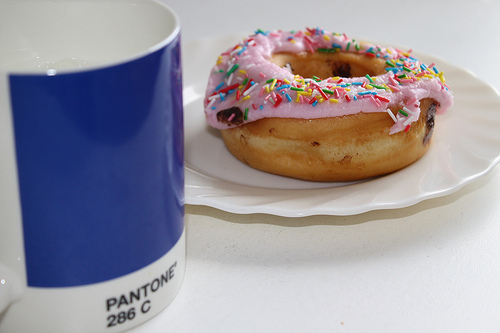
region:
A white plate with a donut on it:
[184, 52, 498, 218]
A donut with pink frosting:
[204, 26, 453, 181]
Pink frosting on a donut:
[204, 29, 453, 135]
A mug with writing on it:
[0, 0, 185, 331]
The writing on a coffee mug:
[104, 263, 178, 328]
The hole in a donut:
[284, 57, 373, 82]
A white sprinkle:
[387, 107, 397, 124]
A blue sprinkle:
[359, 89, 374, 96]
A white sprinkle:
[244, 81, 259, 96]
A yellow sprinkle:
[272, 78, 277, 89]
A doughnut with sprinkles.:
[172, 14, 499, 229]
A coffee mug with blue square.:
[0, 0, 220, 324]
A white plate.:
[175, 103, 494, 225]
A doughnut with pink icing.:
[198, 23, 452, 182]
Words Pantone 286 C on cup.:
[86, 258, 207, 330]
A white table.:
[142, 15, 496, 322]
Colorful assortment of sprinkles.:
[216, 62, 463, 117]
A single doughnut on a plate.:
[178, 8, 498, 255]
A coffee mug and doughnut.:
[0, 3, 499, 331]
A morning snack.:
[0, 1, 486, 320]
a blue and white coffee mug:
[0, 2, 200, 329]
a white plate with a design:
[147, 44, 497, 220]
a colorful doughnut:
[194, 20, 461, 195]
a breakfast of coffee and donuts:
[3, 0, 470, 331]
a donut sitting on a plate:
[151, 11, 498, 234]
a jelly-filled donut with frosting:
[185, 17, 468, 189]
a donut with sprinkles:
[198, 18, 463, 195]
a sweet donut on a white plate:
[140, 14, 498, 231]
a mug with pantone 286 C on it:
[0, 2, 212, 332]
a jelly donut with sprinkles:
[193, 15, 469, 190]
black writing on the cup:
[101, 256, 182, 330]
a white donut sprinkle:
[241, 80, 261, 96]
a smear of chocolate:
[215, 103, 246, 125]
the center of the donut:
[266, 42, 388, 82]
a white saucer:
[181, 35, 498, 226]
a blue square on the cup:
[6, 20, 187, 292]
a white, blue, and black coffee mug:
[1, 0, 191, 331]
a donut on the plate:
[198, 24, 455, 186]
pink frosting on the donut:
[196, 25, 455, 139]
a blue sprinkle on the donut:
[356, 88, 378, 99]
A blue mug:
[0, 2, 187, 315]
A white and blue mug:
[11, 0, 193, 298]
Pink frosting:
[205, 14, 457, 139]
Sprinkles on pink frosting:
[205, 23, 460, 188]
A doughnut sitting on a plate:
[200, 20, 499, 195]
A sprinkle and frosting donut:
[194, 10, 482, 214]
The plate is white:
[193, 7, 498, 232]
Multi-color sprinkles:
[191, 11, 480, 233]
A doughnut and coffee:
[1, 5, 461, 295]